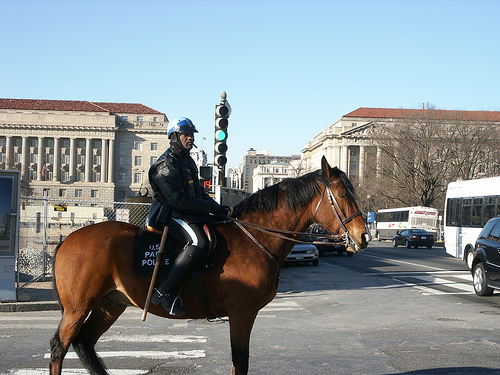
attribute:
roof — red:
[0, 99, 169, 114]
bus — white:
[372, 202, 442, 245]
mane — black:
[229, 170, 327, 218]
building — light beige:
[0, 98, 171, 278]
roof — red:
[339, 103, 499, 120]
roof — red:
[2, 96, 162, 114]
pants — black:
[154, 205, 215, 316]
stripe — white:
[171, 213, 200, 247]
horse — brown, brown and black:
[45, 152, 371, 372]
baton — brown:
[138, 216, 172, 322]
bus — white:
[369, 201, 439, 241]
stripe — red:
[414, 208, 441, 215]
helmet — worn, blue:
[167, 110, 203, 142]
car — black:
[391, 225, 436, 249]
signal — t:
[216, 128, 229, 142]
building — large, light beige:
[303, 104, 497, 234]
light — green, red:
[216, 130, 227, 143]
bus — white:
[445, 175, 499, 263]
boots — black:
[152, 242, 202, 318]